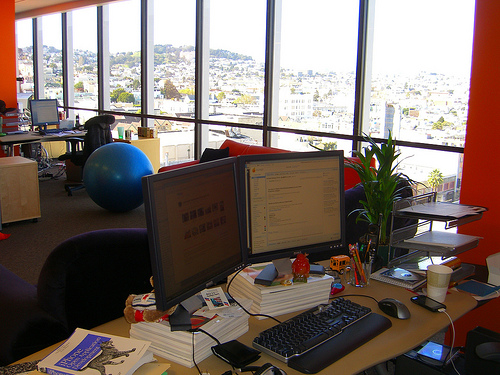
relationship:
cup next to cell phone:
[427, 265, 447, 302] [412, 292, 445, 312]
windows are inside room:
[16, 0, 468, 230] [5, 8, 496, 373]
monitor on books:
[238, 149, 347, 262] [131, 292, 252, 368]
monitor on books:
[238, 149, 347, 262] [226, 259, 329, 321]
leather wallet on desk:
[211, 338, 263, 368] [5, 252, 480, 375]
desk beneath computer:
[192, 274, 465, 362] [125, 146, 352, 283]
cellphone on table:
[410, 294, 447, 312] [404, 327, 421, 340]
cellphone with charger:
[409, 292, 444, 313] [434, 307, 460, 372]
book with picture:
[31, 323, 154, 373] [77, 334, 137, 372]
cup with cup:
[351, 255, 377, 287] [350, 255, 373, 287]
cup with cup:
[350, 255, 373, 287] [351, 255, 377, 287]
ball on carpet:
[81, 141, 154, 211] [0, 164, 145, 281]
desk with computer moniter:
[0, 117, 84, 164] [25, 97, 61, 132]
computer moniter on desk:
[25, 97, 61, 132] [0, 117, 84, 164]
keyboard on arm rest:
[252, 295, 371, 361] [298, 309, 392, 374]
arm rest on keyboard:
[298, 309, 392, 374] [252, 295, 371, 361]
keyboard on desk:
[252, 296, 369, 361] [12, 242, 495, 372]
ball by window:
[81, 141, 154, 213] [35, 16, 142, 79]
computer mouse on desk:
[376, 294, 411, 323] [0, 226, 484, 373]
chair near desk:
[59, 115, 116, 194] [0, 127, 89, 154]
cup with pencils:
[350, 255, 373, 287] [346, 237, 370, 287]